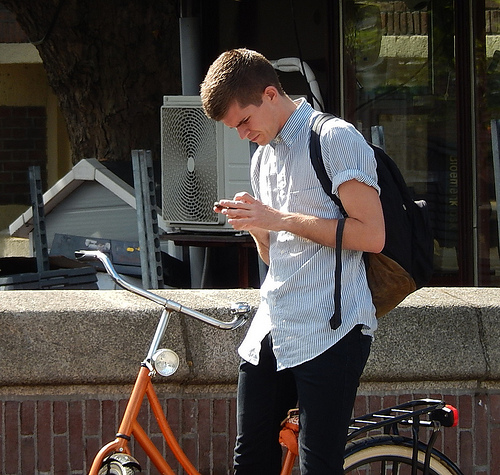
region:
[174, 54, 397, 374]
a man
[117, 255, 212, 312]
bike handle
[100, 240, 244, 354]
bike handle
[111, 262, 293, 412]
bike handle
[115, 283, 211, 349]
bike handle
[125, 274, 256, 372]
bike handle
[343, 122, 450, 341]
black and brown backpack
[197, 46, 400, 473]
a young man standing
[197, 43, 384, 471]
a young man looking at cell phone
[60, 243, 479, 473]
an orange bicycle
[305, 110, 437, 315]
a black and brown backpack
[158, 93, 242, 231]
a large white box fan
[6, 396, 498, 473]
a red brick wall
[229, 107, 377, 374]
a white striped dress shirt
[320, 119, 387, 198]
a rolled up shirt sleeve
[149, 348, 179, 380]
a bicycle head light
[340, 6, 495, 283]
reflections in glass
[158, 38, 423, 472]
man in shirt on bike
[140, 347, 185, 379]
front light of bicycle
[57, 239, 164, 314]
right handlebar of bike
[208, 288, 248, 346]
left handlebar of bike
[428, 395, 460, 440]
back reflector on bike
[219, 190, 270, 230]
left hand of man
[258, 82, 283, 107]
left ear of man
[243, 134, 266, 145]
mouth on man's face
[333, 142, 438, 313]
black bookbag on man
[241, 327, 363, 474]
black pants on man